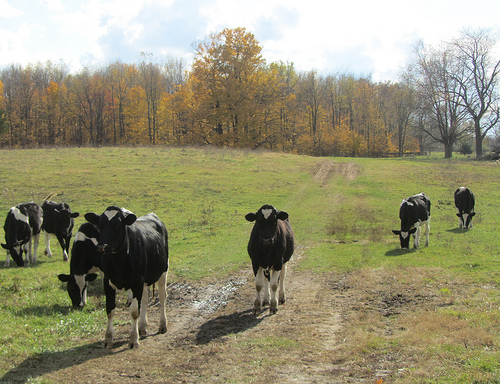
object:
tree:
[411, 50, 468, 157]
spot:
[261, 208, 272, 219]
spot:
[104, 209, 117, 219]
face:
[255, 204, 278, 244]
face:
[97, 207, 123, 256]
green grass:
[274, 169, 294, 196]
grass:
[469, 349, 497, 381]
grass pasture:
[109, 145, 268, 205]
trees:
[0, 66, 35, 151]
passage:
[215, 135, 395, 380]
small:
[459, 141, 472, 155]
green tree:
[460, 143, 470, 156]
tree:
[326, 118, 350, 155]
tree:
[366, 117, 393, 157]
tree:
[253, 70, 293, 149]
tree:
[186, 25, 263, 146]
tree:
[160, 77, 202, 142]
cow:
[391, 191, 431, 251]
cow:
[243, 203, 294, 315]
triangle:
[260, 207, 274, 219]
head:
[245, 203, 289, 245]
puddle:
[223, 280, 243, 289]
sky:
[283, 15, 432, 72]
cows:
[452, 183, 477, 230]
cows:
[83, 203, 170, 350]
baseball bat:
[397, 126, 407, 154]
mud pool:
[170, 284, 227, 316]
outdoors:
[0, 0, 500, 384]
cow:
[0, 202, 45, 266]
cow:
[58, 222, 103, 309]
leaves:
[213, 28, 248, 55]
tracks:
[300, 153, 379, 384]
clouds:
[313, 2, 398, 43]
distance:
[397, 108, 497, 156]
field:
[0, 157, 500, 384]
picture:
[0, 0, 500, 384]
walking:
[57, 207, 294, 348]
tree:
[440, 31, 500, 154]